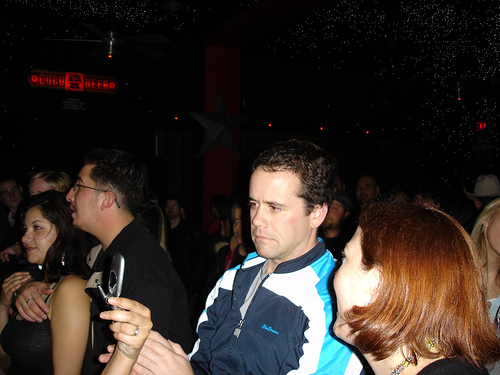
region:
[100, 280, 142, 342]
someone is holding the camera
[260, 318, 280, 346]
the coat is dark blue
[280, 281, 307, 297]
the coat is white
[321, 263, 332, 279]
the coat is light blue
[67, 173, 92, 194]
he is wearing glasses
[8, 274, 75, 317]
his arm is around her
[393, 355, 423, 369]
she is wearing a necklace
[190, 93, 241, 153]
the star is on the wall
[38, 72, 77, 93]
the sign is red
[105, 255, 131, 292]
the phone is silver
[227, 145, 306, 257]
face of the person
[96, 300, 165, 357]
hand of the girl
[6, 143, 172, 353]
a man holding the women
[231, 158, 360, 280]
a man looking seriously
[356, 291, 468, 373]
hairs of the girl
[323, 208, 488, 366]
a girl laughing at other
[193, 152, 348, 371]
a man wearing jacket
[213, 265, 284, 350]
zip of the shirt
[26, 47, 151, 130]
a red light on top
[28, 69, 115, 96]
a red neon light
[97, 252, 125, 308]
a silver cell phone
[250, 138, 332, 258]
man with short brown hair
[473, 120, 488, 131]
an exit sign over a door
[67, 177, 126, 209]
man wearing glasses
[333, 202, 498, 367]
woman with red hair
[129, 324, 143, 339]
a silver ring on a finger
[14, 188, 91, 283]
a woman with brown hair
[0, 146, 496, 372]
two couples next to each other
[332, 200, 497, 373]
woman with red hair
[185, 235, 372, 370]
blue, aqua, white and black jacket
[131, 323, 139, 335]
ring on a woman's left hand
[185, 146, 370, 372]
man wearing a jacket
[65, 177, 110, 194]
eyeglasses man is wearing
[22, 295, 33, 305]
ring on man's finger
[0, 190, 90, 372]
woman standing next to the man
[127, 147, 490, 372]
man and woman watching something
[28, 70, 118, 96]
red print against a black background